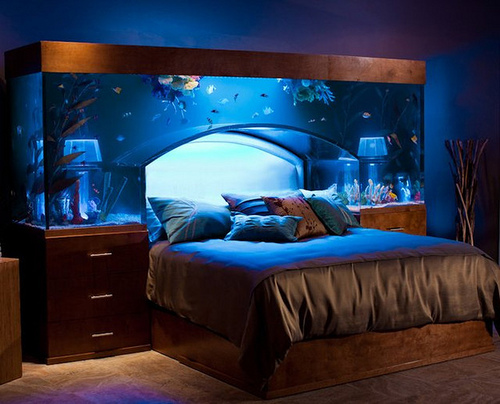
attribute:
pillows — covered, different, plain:
[143, 207, 376, 237]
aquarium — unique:
[25, 35, 433, 221]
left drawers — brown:
[26, 237, 168, 353]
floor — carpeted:
[15, 373, 210, 403]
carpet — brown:
[286, 389, 480, 402]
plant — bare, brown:
[422, 140, 498, 273]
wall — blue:
[13, 11, 425, 67]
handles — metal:
[73, 249, 126, 267]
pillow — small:
[230, 211, 303, 248]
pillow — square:
[260, 198, 327, 238]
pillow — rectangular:
[155, 201, 232, 256]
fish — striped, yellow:
[382, 184, 405, 199]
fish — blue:
[155, 106, 160, 127]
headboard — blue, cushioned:
[158, 158, 300, 216]